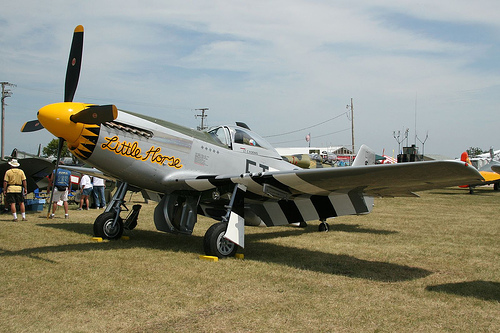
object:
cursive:
[101, 136, 184, 170]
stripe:
[185, 173, 375, 227]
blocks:
[199, 255, 219, 261]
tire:
[203, 222, 239, 259]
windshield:
[235, 129, 262, 147]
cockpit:
[207, 121, 283, 160]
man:
[4, 159, 28, 221]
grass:
[1, 188, 500, 332]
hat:
[8, 159, 21, 168]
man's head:
[7, 159, 20, 168]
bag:
[55, 185, 66, 191]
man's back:
[56, 170, 70, 187]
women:
[76, 174, 93, 211]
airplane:
[19, 24, 484, 257]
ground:
[0, 186, 500, 331]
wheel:
[93, 212, 124, 240]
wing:
[162, 160, 486, 192]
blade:
[64, 24, 85, 101]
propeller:
[20, 25, 118, 133]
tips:
[74, 25, 85, 33]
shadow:
[0, 224, 500, 302]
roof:
[274, 146, 356, 157]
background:
[0, 0, 500, 160]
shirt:
[4, 168, 26, 194]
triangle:
[81, 128, 99, 136]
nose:
[37, 101, 72, 127]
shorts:
[6, 192, 25, 203]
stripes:
[92, 113, 97, 119]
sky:
[0, 0, 500, 172]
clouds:
[1, 1, 498, 77]